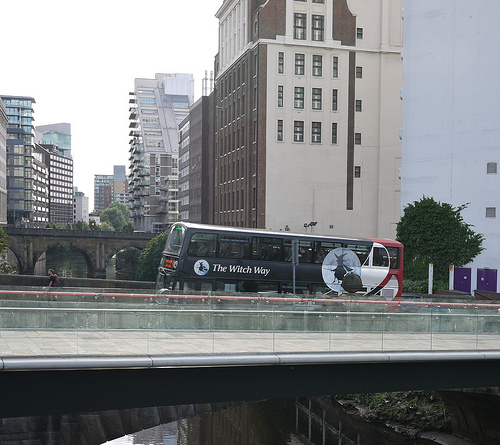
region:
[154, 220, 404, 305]
black double decker bus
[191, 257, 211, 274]
moon and witch graphic on a bus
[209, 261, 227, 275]
white print on the side of a bus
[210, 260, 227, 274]
white print on a bus reading The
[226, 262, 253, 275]
white print on a bus reading Witch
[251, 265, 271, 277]
white print on a bus reading Way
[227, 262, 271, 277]
white print on a bus reading Witch Way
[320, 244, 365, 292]
large witch and moon graphic on a bus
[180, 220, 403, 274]
upper level of a double decker bus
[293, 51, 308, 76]
window on a tan building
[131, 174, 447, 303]
a bus on the road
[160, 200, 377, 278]
side windows on the bus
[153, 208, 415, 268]
the top of the bus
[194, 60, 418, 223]
a big brown building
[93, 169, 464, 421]
a bus on the bridge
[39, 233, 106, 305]
a man walking down the street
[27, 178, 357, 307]
a man walking near a bus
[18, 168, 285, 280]
a bridge near some buildings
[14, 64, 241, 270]
very tall building in the background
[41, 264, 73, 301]
a man wearing a black shirt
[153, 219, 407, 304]
double decker bus on overpass highway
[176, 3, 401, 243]
brown and white building behind bus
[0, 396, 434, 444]
water under over pass highway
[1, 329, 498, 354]
walk way on side of highway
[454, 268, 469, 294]
purple doors on white building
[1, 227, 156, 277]
over pass bridge across the water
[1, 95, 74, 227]
buildings on left side in background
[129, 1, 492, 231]
buildings on right side behind bus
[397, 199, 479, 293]
large green tree behind bus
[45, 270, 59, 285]
man walking on walkway in front of bus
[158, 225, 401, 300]
A bus on the road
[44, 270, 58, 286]
A person near the bus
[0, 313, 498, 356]
A railing on the bridge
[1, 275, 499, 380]
A bridge above the water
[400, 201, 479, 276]
A tree near the bus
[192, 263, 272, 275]
A logo on the bus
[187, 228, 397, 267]
Windows on the bus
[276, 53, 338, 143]
Windows on the side of the building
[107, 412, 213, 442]
Water under the bridge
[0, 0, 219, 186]
The sky above the buildings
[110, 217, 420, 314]
this is a bus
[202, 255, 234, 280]
a word on the bus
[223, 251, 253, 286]
a word on the bus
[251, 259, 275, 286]
a word on the bus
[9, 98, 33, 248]
this is a bulding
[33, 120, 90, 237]
this is a bulding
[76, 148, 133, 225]
this is a bulding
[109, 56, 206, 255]
this is a bulding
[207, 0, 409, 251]
this is a bulding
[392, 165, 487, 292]
this is a tree